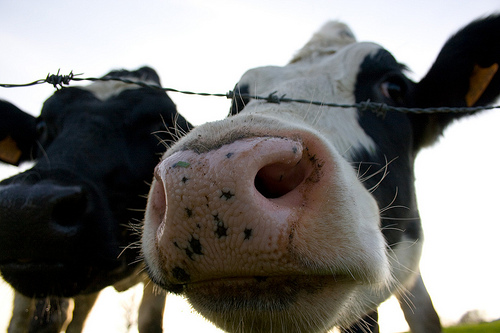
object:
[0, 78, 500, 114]
wire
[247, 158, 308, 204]
nostrils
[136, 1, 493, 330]
cow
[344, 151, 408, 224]
whiskers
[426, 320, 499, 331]
grass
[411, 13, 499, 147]
ear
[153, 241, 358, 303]
mouth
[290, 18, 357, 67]
hump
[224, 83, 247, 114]
eyes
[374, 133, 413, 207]
fur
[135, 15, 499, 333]
head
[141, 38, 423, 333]
face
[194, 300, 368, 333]
whiskers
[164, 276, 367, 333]
chin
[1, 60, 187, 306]
cow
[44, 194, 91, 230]
nostril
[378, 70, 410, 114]
eye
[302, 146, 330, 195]
dirt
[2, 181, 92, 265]
nose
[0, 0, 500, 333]
background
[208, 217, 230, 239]
spots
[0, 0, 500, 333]
sky